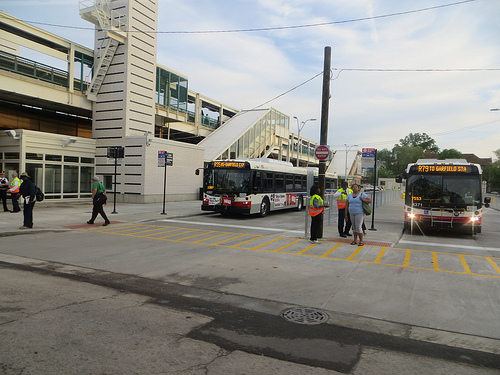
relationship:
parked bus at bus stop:
[399, 153, 484, 232] [94, 140, 484, 290]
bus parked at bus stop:
[194, 156, 321, 222] [192, 141, 481, 249]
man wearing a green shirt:
[86, 176, 110, 227] [89, 181, 104, 193]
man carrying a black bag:
[86, 176, 110, 227] [94, 187, 110, 209]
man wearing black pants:
[86, 176, 110, 227] [86, 192, 112, 226]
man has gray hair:
[86, 170, 112, 224] [88, 171, 103, 181]